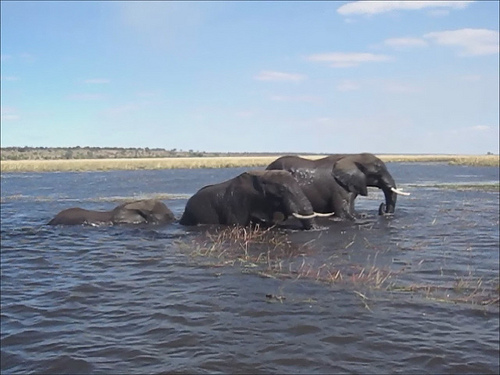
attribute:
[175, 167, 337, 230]
elephant — wet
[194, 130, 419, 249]
elephant — grey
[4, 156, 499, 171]
vegetation — brown, river bank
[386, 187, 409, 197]
elephant tusk — right tusk